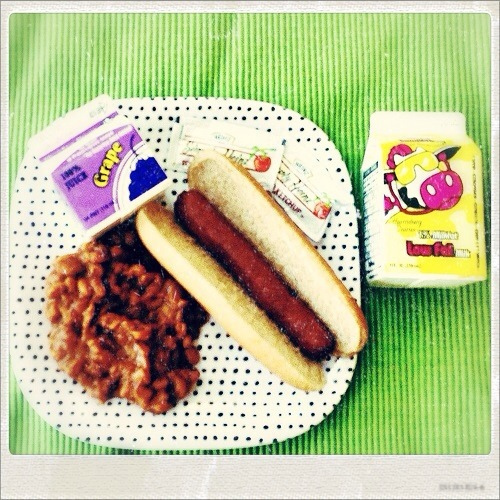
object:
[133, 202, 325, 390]
bun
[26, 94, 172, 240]
juice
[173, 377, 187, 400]
beans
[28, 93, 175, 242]
carton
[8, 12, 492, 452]
place mat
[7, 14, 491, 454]
table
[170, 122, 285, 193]
ketchup packages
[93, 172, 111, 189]
yellow lettering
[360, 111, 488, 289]
carton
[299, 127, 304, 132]
dot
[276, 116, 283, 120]
dot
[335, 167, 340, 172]
dot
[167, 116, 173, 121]
dot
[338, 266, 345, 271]
dot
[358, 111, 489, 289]
milk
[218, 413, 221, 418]
dots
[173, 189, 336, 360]
weiner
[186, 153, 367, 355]
bun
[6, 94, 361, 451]
plate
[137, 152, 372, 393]
hotdog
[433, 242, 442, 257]
lettering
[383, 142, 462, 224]
cow